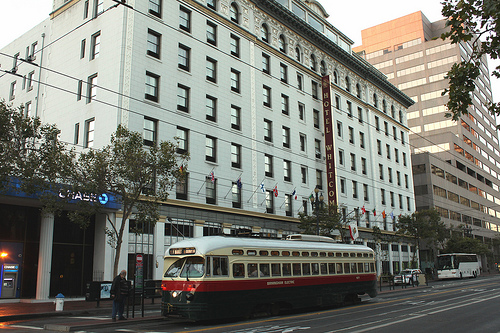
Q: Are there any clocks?
A: No, there are no clocks.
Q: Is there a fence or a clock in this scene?
A: No, there are no clocks or fences.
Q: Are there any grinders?
A: No, there are no grinders.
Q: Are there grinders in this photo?
A: No, there are no grinders.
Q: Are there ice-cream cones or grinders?
A: No, there are no grinders or ice-cream cones.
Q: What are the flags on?
A: The flags are on the building.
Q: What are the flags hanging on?
A: The flags are hanging on the building.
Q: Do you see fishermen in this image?
A: No, there are no fishermen.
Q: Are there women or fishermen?
A: No, there are no fishermen or women.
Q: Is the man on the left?
A: Yes, the man is on the left of the image.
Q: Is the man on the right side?
A: No, the man is on the left of the image.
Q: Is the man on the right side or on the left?
A: The man is on the left of the image.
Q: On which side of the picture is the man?
A: The man is on the left of the image.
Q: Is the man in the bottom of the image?
A: Yes, the man is in the bottom of the image.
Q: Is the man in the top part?
A: No, the man is in the bottom of the image.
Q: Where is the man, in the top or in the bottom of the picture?
A: The man is in the bottom of the image.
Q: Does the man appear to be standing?
A: Yes, the man is standing.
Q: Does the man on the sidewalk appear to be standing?
A: Yes, the man is standing.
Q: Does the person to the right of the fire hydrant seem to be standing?
A: Yes, the man is standing.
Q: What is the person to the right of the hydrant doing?
A: The man is standing.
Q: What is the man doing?
A: The man is standing.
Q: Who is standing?
A: The man is standing.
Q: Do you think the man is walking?
A: No, the man is standing.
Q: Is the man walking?
A: No, the man is standing.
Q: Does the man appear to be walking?
A: No, the man is standing.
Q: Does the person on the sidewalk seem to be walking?
A: No, the man is standing.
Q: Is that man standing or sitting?
A: The man is standing.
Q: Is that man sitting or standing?
A: The man is standing.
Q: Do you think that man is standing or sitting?
A: The man is standing.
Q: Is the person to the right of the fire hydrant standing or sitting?
A: The man is standing.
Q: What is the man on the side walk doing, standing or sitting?
A: The man is standing.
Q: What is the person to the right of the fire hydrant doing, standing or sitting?
A: The man is standing.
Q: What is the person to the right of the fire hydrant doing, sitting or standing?
A: The man is standing.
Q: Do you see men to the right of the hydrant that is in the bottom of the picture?
A: Yes, there is a man to the right of the hydrant.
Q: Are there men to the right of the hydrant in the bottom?
A: Yes, there is a man to the right of the hydrant.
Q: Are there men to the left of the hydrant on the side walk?
A: No, the man is to the right of the hydrant.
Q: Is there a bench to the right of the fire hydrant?
A: No, there is a man to the right of the fire hydrant.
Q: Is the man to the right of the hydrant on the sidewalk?
A: Yes, the man is to the right of the fire hydrant.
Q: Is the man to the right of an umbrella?
A: No, the man is to the right of the fire hydrant.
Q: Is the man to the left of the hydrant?
A: No, the man is to the right of the hydrant.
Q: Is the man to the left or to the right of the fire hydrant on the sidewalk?
A: The man is to the right of the fire hydrant.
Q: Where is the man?
A: The man is on the sidewalk.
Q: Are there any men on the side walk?
A: Yes, there is a man on the side walk.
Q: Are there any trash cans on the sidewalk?
A: No, there is a man on the sidewalk.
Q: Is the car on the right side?
A: Yes, the car is on the right of the image.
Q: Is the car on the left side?
A: No, the car is on the right of the image.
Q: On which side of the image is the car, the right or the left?
A: The car is on the right of the image.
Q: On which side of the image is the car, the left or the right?
A: The car is on the right of the image.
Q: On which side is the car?
A: The car is on the right of the image.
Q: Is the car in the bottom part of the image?
A: Yes, the car is in the bottom of the image.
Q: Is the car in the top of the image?
A: No, the car is in the bottom of the image.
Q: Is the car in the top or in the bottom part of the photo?
A: The car is in the bottom of the image.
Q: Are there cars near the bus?
A: Yes, there is a car near the bus.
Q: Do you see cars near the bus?
A: Yes, there is a car near the bus.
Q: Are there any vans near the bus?
A: No, there is a car near the bus.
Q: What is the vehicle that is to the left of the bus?
A: The vehicle is a car.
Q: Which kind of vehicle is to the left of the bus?
A: The vehicle is a car.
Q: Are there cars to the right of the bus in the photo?
A: No, the car is to the left of the bus.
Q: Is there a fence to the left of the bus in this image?
A: No, there is a car to the left of the bus.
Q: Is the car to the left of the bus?
A: Yes, the car is to the left of the bus.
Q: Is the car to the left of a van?
A: No, the car is to the left of the bus.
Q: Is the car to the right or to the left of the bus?
A: The car is to the left of the bus.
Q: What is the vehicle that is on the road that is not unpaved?
A: The vehicle is a car.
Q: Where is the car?
A: The car is on the road.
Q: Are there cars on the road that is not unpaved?
A: Yes, there is a car on the road.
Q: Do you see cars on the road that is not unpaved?
A: Yes, there is a car on the road.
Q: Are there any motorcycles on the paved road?
A: No, there is a car on the road.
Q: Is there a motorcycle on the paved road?
A: No, there is a car on the road.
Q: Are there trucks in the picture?
A: No, there are no trucks.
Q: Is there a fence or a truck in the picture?
A: No, there are no trucks or fences.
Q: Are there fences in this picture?
A: No, there are no fences.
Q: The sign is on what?
A: The sign is on the building.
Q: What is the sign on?
A: The sign is on the building.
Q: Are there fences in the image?
A: No, there are no fences.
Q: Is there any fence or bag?
A: No, there are no fences or bags.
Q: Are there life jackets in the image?
A: No, there are no life jackets.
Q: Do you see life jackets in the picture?
A: No, there are no life jackets.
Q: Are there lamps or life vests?
A: No, there are no life vests or lamps.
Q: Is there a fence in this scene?
A: No, there are no fences.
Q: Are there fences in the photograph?
A: No, there are no fences.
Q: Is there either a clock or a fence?
A: No, there are no fences or clocks.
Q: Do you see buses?
A: Yes, there is a bus.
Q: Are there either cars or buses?
A: Yes, there is a bus.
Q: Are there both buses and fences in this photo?
A: No, there is a bus but no fences.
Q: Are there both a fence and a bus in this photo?
A: No, there is a bus but no fences.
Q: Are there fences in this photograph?
A: No, there are no fences.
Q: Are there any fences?
A: No, there are no fences.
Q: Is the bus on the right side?
A: Yes, the bus is on the right of the image.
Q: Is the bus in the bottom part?
A: Yes, the bus is in the bottom of the image.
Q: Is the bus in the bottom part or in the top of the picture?
A: The bus is in the bottom of the image.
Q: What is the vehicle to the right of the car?
A: The vehicle is a bus.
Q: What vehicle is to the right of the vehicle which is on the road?
A: The vehicle is a bus.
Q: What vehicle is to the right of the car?
A: The vehicle is a bus.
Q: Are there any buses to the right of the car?
A: Yes, there is a bus to the right of the car.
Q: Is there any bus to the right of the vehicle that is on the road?
A: Yes, there is a bus to the right of the car.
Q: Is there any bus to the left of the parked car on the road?
A: No, the bus is to the right of the car.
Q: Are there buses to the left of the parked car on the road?
A: No, the bus is to the right of the car.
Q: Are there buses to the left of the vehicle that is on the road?
A: No, the bus is to the right of the car.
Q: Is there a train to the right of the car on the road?
A: No, there is a bus to the right of the car.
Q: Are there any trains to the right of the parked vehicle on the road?
A: No, there is a bus to the right of the car.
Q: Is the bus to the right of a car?
A: Yes, the bus is to the right of a car.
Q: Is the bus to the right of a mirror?
A: No, the bus is to the right of a car.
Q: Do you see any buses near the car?
A: Yes, there is a bus near the car.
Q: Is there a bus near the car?
A: Yes, there is a bus near the car.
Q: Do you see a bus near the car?
A: Yes, there is a bus near the car.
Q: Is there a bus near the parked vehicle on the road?
A: Yes, there is a bus near the car.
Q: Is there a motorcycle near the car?
A: No, there is a bus near the car.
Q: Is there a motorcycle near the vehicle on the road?
A: No, there is a bus near the car.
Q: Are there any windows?
A: Yes, there are windows.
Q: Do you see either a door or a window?
A: Yes, there are windows.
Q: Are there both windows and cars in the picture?
A: Yes, there are both windows and a car.